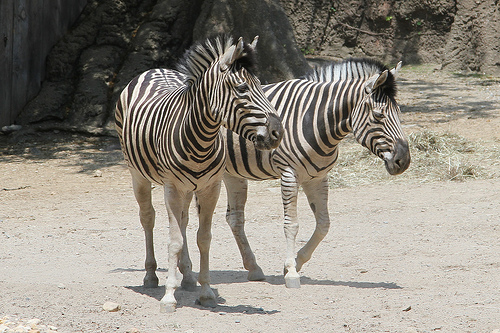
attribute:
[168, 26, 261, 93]
mane — long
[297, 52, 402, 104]
mane — long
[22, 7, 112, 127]
rock — big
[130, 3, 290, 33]
rock — big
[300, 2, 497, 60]
rock — big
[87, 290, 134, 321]
rocks — small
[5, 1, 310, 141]
boulder — large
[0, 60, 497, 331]
ground — dry, dirt